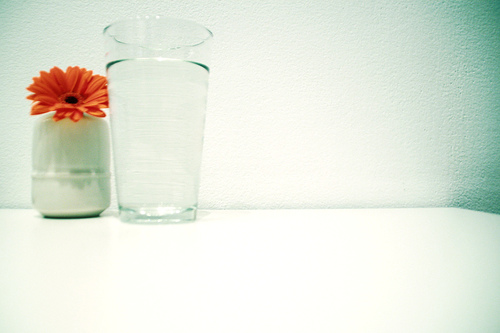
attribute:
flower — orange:
[26, 67, 108, 123]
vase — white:
[31, 111, 114, 221]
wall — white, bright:
[1, 1, 484, 213]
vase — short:
[28, 112, 109, 225]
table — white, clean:
[17, 193, 476, 326]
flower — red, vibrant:
[25, 63, 110, 124]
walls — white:
[13, 19, 483, 204]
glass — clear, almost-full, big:
[100, 14, 220, 224]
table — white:
[12, 210, 446, 316]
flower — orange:
[27, 65, 107, 119]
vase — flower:
[25, 120, 112, 220]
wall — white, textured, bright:
[3, 12, 459, 203]